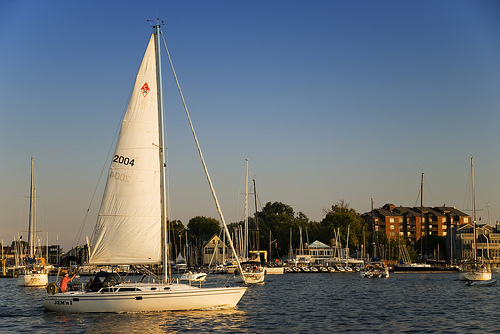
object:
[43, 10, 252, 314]
boat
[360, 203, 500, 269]
building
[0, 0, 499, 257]
sky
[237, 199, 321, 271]
tree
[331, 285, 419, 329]
water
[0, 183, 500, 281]
town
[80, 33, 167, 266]
sail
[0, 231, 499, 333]
harbor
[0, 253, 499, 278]
shoreline